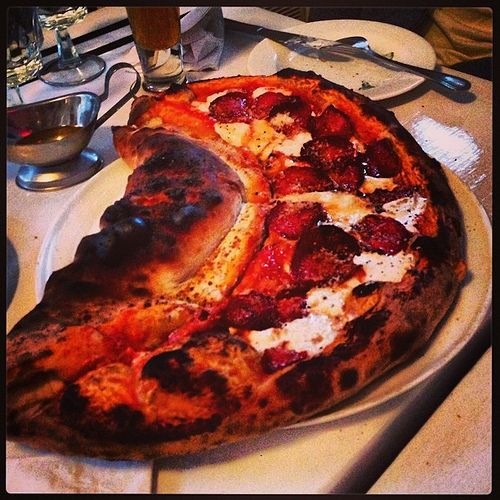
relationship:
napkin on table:
[5, 435, 155, 496] [8, 4, 492, 499]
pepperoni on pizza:
[352, 213, 410, 254] [7, 66, 466, 463]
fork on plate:
[323, 36, 471, 91] [247, 18, 438, 102]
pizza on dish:
[7, 66, 466, 463] [34, 158, 492, 430]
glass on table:
[122, 4, 189, 94] [8, 4, 492, 499]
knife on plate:
[209, 13, 386, 64] [247, 18, 438, 102]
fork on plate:
[322, 33, 474, 98] [247, 18, 438, 102]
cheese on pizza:
[268, 289, 335, 342] [17, 75, 409, 452]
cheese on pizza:
[324, 160, 412, 248] [17, 75, 409, 452]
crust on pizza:
[388, 115, 466, 361] [7, 66, 466, 463]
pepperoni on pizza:
[306, 127, 349, 164] [7, 66, 466, 463]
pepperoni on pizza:
[295, 220, 351, 280] [7, 66, 466, 463]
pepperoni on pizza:
[349, 209, 409, 254] [7, 66, 466, 463]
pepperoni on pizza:
[363, 133, 403, 180] [7, 66, 466, 463]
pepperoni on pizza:
[299, 96, 350, 141] [7, 66, 466, 463]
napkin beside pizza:
[5, 435, 155, 496] [17, 75, 409, 452]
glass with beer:
[122, 4, 189, 94] [123, 7, 190, 87]